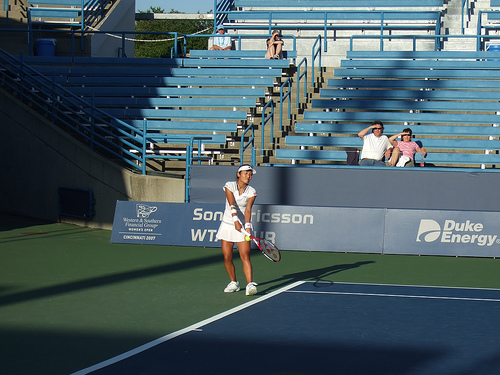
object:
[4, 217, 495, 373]
court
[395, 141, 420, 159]
shirt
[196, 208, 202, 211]
white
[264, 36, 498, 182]
bleachers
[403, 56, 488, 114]
stands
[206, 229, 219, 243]
letter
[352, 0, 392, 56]
man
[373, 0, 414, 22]
hands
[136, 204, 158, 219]
graphic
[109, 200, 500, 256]
wall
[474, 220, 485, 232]
white letter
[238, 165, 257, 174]
visor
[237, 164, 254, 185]
head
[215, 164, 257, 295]
player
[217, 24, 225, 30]
hat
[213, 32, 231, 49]
shirt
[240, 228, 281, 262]
racket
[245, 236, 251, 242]
ball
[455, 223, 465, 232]
letter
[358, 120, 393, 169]
man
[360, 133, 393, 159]
shirt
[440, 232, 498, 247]
letter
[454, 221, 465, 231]
white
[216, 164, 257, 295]
asian woman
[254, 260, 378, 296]
shadow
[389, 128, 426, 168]
people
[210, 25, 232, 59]
man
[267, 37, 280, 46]
shirt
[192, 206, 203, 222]
letter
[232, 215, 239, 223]
objects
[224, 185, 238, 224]
woman's arm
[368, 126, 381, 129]
right hand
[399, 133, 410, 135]
right hand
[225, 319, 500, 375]
part